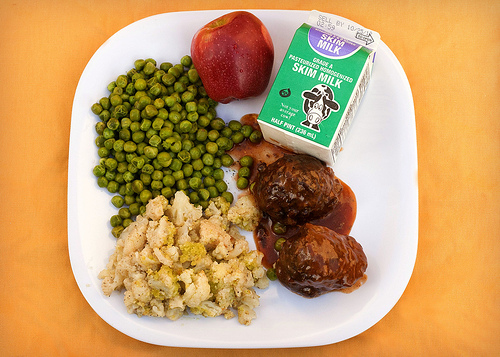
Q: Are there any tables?
A: Yes, there is a table.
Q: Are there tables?
A: Yes, there is a table.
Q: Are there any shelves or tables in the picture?
A: Yes, there is a table.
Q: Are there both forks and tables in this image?
A: No, there is a table but no forks.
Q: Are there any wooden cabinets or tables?
A: Yes, there is a wood table.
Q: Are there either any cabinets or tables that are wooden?
A: Yes, the table is wooden.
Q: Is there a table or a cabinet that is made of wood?
A: Yes, the table is made of wood.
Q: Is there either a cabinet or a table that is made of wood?
A: Yes, the table is made of wood.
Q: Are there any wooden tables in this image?
A: Yes, there is a wood table.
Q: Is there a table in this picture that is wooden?
A: Yes, there is a table that is wooden.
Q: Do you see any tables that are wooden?
A: Yes, there is a table that is wooden.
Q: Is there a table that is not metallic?
A: Yes, there is a wooden table.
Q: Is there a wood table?
A: Yes, there is a table that is made of wood.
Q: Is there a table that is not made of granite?
A: Yes, there is a table that is made of wood.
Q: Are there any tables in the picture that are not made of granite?
A: Yes, there is a table that is made of wood.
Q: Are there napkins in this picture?
A: No, there are no napkins.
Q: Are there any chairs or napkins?
A: No, there are no napkins or chairs.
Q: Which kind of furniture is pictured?
A: The furniture is a table.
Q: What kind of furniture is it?
A: The piece of furniture is a table.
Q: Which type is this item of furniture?
A: This is a table.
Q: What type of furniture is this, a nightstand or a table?
A: This is a table.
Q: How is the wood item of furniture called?
A: The piece of furniture is a table.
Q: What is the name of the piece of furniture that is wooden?
A: The piece of furniture is a table.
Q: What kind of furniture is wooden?
A: The furniture is a table.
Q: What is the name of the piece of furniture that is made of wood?
A: The piece of furniture is a table.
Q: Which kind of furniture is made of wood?
A: The furniture is a table.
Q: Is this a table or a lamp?
A: This is a table.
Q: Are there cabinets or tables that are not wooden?
A: No, there is a table but it is wooden.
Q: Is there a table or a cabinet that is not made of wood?
A: No, there is a table but it is made of wood.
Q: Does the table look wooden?
A: Yes, the table is wooden.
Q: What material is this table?
A: The table is made of wood.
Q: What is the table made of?
A: The table is made of wood.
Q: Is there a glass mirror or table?
A: No, there is a table but it is wooden.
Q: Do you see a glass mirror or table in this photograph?
A: No, there is a table but it is wooden.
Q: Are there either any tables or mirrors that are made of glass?
A: No, there is a table but it is made of wood.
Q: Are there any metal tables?
A: No, there is a table but it is made of wood.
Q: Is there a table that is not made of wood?
A: No, there is a table but it is made of wood.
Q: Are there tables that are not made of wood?
A: No, there is a table but it is made of wood.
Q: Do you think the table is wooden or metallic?
A: The table is wooden.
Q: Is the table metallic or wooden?
A: The table is wooden.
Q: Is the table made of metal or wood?
A: The table is made of wood.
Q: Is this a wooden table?
A: Yes, this is a wooden table.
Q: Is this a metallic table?
A: No, this is a wooden table.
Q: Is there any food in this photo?
A: Yes, there is food.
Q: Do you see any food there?
A: Yes, there is food.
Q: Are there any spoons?
A: No, there are no spoons.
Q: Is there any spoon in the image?
A: No, there are no spoons.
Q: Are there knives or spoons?
A: No, there are no spoons or knives.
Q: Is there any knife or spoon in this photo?
A: No, there are no spoons or knives.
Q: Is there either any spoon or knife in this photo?
A: No, there are no spoons or knives.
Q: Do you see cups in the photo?
A: No, there are no cups.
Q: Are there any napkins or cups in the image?
A: No, there are no cups or napkins.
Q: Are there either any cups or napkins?
A: No, there are no cups or napkins.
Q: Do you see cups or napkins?
A: No, there are no cups or napkins.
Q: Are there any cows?
A: Yes, there is a cow.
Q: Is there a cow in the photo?
A: Yes, there is a cow.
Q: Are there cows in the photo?
A: Yes, there is a cow.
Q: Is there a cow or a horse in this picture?
A: Yes, there is a cow.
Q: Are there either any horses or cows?
A: Yes, there is a cow.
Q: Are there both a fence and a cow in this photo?
A: No, there is a cow but no fences.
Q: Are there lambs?
A: No, there are no lambs.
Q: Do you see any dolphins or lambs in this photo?
A: No, there are no lambs or dolphins.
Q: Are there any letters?
A: Yes, there are letters.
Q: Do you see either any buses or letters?
A: Yes, there are letters.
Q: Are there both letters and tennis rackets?
A: No, there are letters but no rackets.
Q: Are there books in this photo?
A: No, there are no books.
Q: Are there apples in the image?
A: Yes, there is an apple.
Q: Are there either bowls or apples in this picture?
A: Yes, there is an apple.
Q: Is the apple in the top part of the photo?
A: Yes, the apple is in the top of the image.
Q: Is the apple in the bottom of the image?
A: No, the apple is in the top of the image.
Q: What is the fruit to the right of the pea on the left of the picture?
A: The fruit is an apple.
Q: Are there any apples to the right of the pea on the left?
A: Yes, there is an apple to the right of the pea.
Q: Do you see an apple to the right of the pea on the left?
A: Yes, there is an apple to the right of the pea.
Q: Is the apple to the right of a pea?
A: Yes, the apple is to the right of a pea.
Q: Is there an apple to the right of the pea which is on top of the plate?
A: Yes, there is an apple to the right of the pea.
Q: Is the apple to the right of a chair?
A: No, the apple is to the right of a pea.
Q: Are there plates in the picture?
A: Yes, there is a plate.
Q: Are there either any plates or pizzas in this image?
A: Yes, there is a plate.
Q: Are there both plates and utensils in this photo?
A: No, there is a plate but no utensils.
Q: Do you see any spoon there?
A: No, there are no spoons.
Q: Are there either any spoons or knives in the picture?
A: No, there are no spoons or knives.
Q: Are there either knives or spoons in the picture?
A: No, there are no spoons or knives.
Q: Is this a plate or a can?
A: This is a plate.